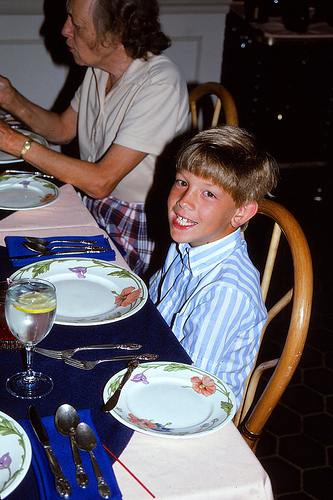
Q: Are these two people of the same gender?
A: No, they are both male and female.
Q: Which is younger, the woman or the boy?
A: The boy is younger than the woman.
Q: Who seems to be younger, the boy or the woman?
A: The boy is younger than the woman.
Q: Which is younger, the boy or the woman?
A: The boy is younger than the woman.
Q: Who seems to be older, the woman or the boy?
A: The woman is older than the boy.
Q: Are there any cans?
A: No, there are no cans.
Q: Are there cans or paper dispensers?
A: No, there are no cans or paper dispensers.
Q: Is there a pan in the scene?
A: No, there are no pans.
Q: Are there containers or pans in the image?
A: No, there are no pans or containers.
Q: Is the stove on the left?
A: No, the stove is on the right of the image.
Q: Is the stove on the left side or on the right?
A: The stove is on the right of the image.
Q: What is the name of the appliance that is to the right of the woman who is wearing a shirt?
A: The appliance is a stove.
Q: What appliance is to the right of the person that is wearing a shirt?
A: The appliance is a stove.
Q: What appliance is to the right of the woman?
A: The appliance is a stove.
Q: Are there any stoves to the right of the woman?
A: Yes, there is a stove to the right of the woman.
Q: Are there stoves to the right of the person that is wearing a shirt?
A: Yes, there is a stove to the right of the woman.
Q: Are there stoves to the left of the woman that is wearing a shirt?
A: No, the stove is to the right of the woman.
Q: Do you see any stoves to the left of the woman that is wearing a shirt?
A: No, the stove is to the right of the woman.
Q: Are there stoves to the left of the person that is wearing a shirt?
A: No, the stove is to the right of the woman.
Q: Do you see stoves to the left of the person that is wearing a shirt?
A: No, the stove is to the right of the woman.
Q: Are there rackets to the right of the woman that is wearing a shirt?
A: No, there is a stove to the right of the woman.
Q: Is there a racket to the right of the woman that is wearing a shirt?
A: No, there is a stove to the right of the woman.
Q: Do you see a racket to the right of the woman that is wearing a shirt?
A: No, there is a stove to the right of the woman.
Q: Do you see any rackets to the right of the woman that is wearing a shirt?
A: No, there is a stove to the right of the woman.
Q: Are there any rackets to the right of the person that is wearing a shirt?
A: No, there is a stove to the right of the woman.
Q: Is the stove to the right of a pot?
A: No, the stove is to the right of the woman.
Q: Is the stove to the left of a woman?
A: No, the stove is to the right of a woman.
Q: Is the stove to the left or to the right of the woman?
A: The stove is to the right of the woman.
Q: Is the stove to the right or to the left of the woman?
A: The stove is to the right of the woman.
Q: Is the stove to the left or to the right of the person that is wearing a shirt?
A: The stove is to the right of the woman.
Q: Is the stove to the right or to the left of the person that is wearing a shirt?
A: The stove is to the right of the woman.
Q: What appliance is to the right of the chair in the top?
A: The appliance is a stove.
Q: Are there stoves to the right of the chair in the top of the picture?
A: Yes, there is a stove to the right of the chair.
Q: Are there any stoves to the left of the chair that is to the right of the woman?
A: No, the stove is to the right of the chair.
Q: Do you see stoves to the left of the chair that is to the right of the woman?
A: No, the stove is to the right of the chair.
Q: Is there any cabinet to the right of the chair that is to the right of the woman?
A: No, there is a stove to the right of the chair.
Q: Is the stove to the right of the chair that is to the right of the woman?
A: Yes, the stove is to the right of the chair.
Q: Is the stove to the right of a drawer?
A: No, the stove is to the right of the chair.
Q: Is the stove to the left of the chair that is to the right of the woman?
A: No, the stove is to the right of the chair.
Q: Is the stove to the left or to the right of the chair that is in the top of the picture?
A: The stove is to the right of the chair.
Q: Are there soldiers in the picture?
A: No, there are no soldiers.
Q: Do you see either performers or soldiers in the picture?
A: No, there are no soldiers or performers.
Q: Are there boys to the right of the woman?
A: Yes, there is a boy to the right of the woman.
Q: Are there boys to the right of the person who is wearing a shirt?
A: Yes, there is a boy to the right of the woman.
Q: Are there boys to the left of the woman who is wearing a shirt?
A: No, the boy is to the right of the woman.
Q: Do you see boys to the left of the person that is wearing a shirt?
A: No, the boy is to the right of the woman.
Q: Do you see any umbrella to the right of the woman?
A: No, there is a boy to the right of the woman.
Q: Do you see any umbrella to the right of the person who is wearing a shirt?
A: No, there is a boy to the right of the woman.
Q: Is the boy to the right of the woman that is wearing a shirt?
A: Yes, the boy is to the right of the woman.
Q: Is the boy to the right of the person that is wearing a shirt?
A: Yes, the boy is to the right of the woman.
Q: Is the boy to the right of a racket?
A: No, the boy is to the right of the woman.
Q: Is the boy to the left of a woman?
A: No, the boy is to the right of a woman.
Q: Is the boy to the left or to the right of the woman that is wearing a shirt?
A: The boy is to the right of the woman.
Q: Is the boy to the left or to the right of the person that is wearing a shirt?
A: The boy is to the right of the woman.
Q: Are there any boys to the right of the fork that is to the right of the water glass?
A: Yes, there is a boy to the right of the fork.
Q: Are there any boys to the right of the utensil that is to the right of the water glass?
A: Yes, there is a boy to the right of the fork.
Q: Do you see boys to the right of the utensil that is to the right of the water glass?
A: Yes, there is a boy to the right of the fork.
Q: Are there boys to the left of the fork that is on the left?
A: No, the boy is to the right of the fork.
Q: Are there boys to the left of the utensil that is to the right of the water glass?
A: No, the boy is to the right of the fork.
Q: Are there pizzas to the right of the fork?
A: No, there is a boy to the right of the fork.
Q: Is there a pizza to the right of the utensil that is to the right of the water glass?
A: No, there is a boy to the right of the fork.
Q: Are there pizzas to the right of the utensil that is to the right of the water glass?
A: No, there is a boy to the right of the fork.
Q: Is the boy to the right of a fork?
A: Yes, the boy is to the right of a fork.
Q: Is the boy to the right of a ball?
A: No, the boy is to the right of a fork.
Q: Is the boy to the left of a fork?
A: No, the boy is to the right of a fork.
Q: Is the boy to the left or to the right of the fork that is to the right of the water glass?
A: The boy is to the right of the fork.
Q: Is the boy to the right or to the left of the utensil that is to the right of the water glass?
A: The boy is to the right of the fork.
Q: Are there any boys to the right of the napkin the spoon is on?
A: Yes, there is a boy to the right of the napkin.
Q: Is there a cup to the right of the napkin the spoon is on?
A: No, there is a boy to the right of the napkin.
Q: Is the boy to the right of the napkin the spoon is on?
A: Yes, the boy is to the right of the napkin.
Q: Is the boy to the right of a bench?
A: No, the boy is to the right of the napkin.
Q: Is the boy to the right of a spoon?
A: Yes, the boy is to the right of a spoon.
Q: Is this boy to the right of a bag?
A: No, the boy is to the right of a spoon.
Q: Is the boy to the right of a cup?
A: No, the boy is to the right of the plate.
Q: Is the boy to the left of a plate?
A: No, the boy is to the right of a plate.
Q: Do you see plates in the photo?
A: Yes, there is a plate.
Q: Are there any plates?
A: Yes, there is a plate.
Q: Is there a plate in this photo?
A: Yes, there is a plate.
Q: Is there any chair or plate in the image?
A: Yes, there is a plate.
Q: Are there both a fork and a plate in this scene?
A: Yes, there are both a plate and a fork.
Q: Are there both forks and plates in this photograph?
A: Yes, there are both a plate and a fork.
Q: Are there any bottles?
A: No, there are no bottles.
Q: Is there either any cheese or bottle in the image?
A: No, there are no bottles or cheese.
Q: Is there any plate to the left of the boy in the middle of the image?
A: Yes, there is a plate to the left of the boy.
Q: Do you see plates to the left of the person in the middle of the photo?
A: Yes, there is a plate to the left of the boy.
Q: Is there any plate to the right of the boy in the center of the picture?
A: No, the plate is to the left of the boy.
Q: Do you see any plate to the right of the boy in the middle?
A: No, the plate is to the left of the boy.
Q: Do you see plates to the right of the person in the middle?
A: No, the plate is to the left of the boy.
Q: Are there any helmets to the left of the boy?
A: No, there is a plate to the left of the boy.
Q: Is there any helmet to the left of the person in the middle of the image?
A: No, there is a plate to the left of the boy.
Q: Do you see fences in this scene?
A: No, there are no fences.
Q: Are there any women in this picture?
A: Yes, there is a woman.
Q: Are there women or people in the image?
A: Yes, there is a woman.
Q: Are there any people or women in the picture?
A: Yes, there is a woman.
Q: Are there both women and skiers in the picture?
A: No, there is a woman but no skiers.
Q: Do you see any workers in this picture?
A: No, there are no workers.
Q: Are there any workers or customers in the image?
A: No, there are no workers or customers.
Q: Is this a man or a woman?
A: This is a woman.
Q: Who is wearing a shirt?
A: The woman is wearing a shirt.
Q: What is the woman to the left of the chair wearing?
A: The woman is wearing a shirt.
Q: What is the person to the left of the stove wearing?
A: The woman is wearing a shirt.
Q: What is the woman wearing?
A: The woman is wearing a shirt.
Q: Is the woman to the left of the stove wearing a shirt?
A: Yes, the woman is wearing a shirt.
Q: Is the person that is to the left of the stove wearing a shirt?
A: Yes, the woman is wearing a shirt.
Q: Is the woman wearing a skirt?
A: No, the woman is wearing a shirt.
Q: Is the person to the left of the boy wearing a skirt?
A: No, the woman is wearing a shirt.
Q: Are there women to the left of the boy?
A: Yes, there is a woman to the left of the boy.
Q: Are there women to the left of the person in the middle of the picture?
A: Yes, there is a woman to the left of the boy.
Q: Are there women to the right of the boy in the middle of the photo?
A: No, the woman is to the left of the boy.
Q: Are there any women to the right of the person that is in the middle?
A: No, the woman is to the left of the boy.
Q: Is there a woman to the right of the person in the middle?
A: No, the woman is to the left of the boy.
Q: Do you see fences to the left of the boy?
A: No, there is a woman to the left of the boy.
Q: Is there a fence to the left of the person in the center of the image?
A: No, there is a woman to the left of the boy.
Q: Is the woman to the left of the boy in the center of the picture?
A: Yes, the woman is to the left of the boy.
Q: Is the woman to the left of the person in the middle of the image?
A: Yes, the woman is to the left of the boy.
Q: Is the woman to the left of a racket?
A: No, the woman is to the left of the boy.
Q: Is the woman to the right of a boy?
A: No, the woman is to the left of a boy.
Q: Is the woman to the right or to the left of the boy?
A: The woman is to the left of the boy.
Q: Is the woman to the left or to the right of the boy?
A: The woman is to the left of the boy.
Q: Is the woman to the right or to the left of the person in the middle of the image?
A: The woman is to the left of the boy.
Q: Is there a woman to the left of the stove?
A: Yes, there is a woman to the left of the stove.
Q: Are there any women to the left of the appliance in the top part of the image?
A: Yes, there is a woman to the left of the stove.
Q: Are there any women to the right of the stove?
A: No, the woman is to the left of the stove.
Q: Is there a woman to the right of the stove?
A: No, the woman is to the left of the stove.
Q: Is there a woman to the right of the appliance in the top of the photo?
A: No, the woman is to the left of the stove.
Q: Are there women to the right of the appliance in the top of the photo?
A: No, the woman is to the left of the stove.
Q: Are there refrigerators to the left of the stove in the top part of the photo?
A: No, there is a woman to the left of the stove.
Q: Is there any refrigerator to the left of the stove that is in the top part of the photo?
A: No, there is a woman to the left of the stove.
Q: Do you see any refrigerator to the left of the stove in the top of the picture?
A: No, there is a woman to the left of the stove.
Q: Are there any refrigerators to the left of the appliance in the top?
A: No, there is a woman to the left of the stove.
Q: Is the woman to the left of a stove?
A: Yes, the woman is to the left of a stove.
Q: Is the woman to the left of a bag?
A: No, the woman is to the left of a stove.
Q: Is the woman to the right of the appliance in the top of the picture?
A: No, the woman is to the left of the stove.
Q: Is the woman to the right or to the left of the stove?
A: The woman is to the left of the stove.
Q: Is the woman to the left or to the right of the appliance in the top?
A: The woman is to the left of the stove.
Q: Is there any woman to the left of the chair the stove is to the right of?
A: Yes, there is a woman to the left of the chair.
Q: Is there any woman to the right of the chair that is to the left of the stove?
A: No, the woman is to the left of the chair.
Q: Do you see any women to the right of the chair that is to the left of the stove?
A: No, the woman is to the left of the chair.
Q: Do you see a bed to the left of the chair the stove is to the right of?
A: No, there is a woman to the left of the chair.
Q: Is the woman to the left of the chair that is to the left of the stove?
A: Yes, the woman is to the left of the chair.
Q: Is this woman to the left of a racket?
A: No, the woman is to the left of the chair.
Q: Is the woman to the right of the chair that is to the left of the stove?
A: No, the woman is to the left of the chair.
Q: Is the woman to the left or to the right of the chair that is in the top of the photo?
A: The woman is to the left of the chair.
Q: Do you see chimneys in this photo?
A: No, there are no chimneys.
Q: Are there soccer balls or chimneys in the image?
A: No, there are no chimneys or soccer balls.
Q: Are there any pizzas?
A: No, there are no pizzas.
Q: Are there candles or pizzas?
A: No, there are no pizzas or candles.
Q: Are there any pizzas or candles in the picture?
A: No, there are no pizzas or candles.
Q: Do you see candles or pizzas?
A: No, there are no pizzas or candles.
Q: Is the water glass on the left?
A: Yes, the water glass is on the left of the image.